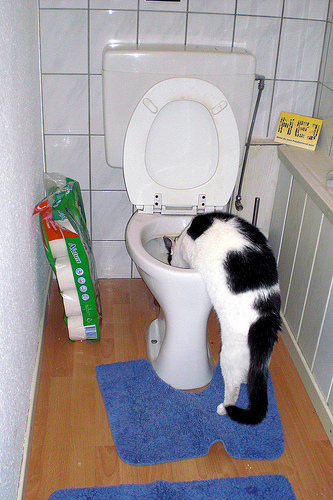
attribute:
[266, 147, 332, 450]
wall boards — white painted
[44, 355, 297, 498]
rugs — 2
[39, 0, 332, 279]
wall — white, tiled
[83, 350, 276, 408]
rug — blue, toilet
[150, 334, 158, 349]
screw — toilet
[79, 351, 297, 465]
mat — blue, restroom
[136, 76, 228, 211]
seat — up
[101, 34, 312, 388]
toliet — white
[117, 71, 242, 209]
lid — toilet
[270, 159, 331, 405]
panels — wood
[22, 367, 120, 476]
flooring — wooden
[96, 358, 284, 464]
mat — blue , bathroom, carpeted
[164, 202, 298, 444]
cat — black, white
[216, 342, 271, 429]
tail — cat's, fluffy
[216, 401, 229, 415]
paw — hind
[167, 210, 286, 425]
cat — black, white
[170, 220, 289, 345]
cat — black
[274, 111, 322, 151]
sign — yellow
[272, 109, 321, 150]
card — yellow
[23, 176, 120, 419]
package — unopened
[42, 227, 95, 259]
rolls — toilet tissue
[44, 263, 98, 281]
rolls — toilet tissue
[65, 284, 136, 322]
rolls — toilet tissue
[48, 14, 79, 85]
tile — rectangular, bathroom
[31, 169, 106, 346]
rolls — toilet paper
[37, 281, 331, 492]
floor — linoluem